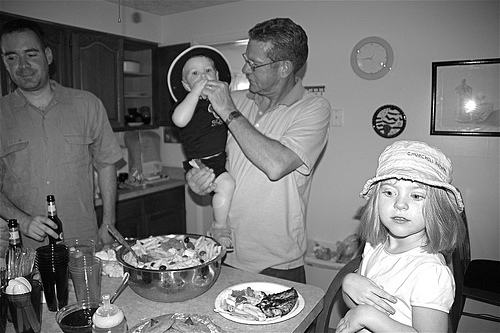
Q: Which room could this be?
A: It is a kitchen.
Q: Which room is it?
A: It is a kitchen.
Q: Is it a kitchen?
A: Yes, it is a kitchen.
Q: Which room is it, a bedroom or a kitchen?
A: It is a kitchen.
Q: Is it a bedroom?
A: No, it is a kitchen.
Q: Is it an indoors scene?
A: Yes, it is indoors.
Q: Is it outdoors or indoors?
A: It is indoors.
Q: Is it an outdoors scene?
A: No, it is indoors.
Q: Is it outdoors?
A: No, it is indoors.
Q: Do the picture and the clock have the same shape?
A: Yes, both the picture and the clock are round.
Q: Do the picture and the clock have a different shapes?
A: No, both the picture and the clock are round.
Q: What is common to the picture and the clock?
A: The shape, both the picture and the clock are round.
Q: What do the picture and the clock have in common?
A: The shape, both the picture and the clock are round.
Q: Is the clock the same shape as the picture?
A: Yes, both the clock and the picture are round.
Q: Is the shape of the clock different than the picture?
A: No, both the clock and the picture are round.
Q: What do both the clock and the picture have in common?
A: The shape, both the clock and the picture are round.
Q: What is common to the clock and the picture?
A: The shape, both the clock and the picture are round.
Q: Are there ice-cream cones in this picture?
A: No, there are no ice-cream cones.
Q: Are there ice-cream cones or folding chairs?
A: No, there are no ice-cream cones or folding chairs.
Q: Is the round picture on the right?
A: Yes, the picture is on the right of the image.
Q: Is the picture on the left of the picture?
A: No, the picture is on the right of the image.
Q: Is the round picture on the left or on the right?
A: The picture is on the right of the image.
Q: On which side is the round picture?
A: The picture is on the right of the image.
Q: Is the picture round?
A: Yes, the picture is round.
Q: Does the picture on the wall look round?
A: Yes, the picture is round.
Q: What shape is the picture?
A: The picture is round.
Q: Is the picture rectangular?
A: No, the picture is round.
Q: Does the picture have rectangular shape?
A: No, the picture is round.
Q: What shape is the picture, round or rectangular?
A: The picture is round.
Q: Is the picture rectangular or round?
A: The picture is round.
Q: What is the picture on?
A: The picture is on the wall.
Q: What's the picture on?
A: The picture is on the wall.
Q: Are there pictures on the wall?
A: Yes, there is a picture on the wall.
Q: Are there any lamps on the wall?
A: No, there is a picture on the wall.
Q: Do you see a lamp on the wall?
A: No, there is a picture on the wall.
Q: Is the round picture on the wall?
A: Yes, the picture is on the wall.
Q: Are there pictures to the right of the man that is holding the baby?
A: Yes, there is a picture to the right of the man.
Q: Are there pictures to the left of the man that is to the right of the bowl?
A: No, the picture is to the right of the man.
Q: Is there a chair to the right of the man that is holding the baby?
A: No, there is a picture to the right of the man.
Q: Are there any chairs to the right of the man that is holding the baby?
A: No, there is a picture to the right of the man.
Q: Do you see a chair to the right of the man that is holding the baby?
A: No, there is a picture to the right of the man.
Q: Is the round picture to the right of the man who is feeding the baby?
A: Yes, the picture is to the right of the man.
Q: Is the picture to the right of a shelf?
A: No, the picture is to the right of the man.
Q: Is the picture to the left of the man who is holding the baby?
A: No, the picture is to the right of the man.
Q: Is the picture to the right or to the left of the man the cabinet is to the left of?
A: The picture is to the right of the man.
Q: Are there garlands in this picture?
A: No, there are no garlands.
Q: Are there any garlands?
A: No, there are no garlands.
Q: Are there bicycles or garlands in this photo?
A: No, there are no garlands or bicycles.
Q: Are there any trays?
A: No, there are no trays.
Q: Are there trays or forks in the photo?
A: No, there are no trays or forks.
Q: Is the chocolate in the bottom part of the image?
A: Yes, the chocolate is in the bottom of the image.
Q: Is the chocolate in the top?
A: No, the chocolate is in the bottom of the image.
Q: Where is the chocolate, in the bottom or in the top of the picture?
A: The chocolate is in the bottom of the image.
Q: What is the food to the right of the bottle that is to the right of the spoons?
A: The food is chocolate.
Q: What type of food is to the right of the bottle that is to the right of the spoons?
A: The food is chocolate.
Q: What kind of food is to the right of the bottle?
A: The food is chocolate.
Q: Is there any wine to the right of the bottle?
A: No, there is chocolate to the right of the bottle.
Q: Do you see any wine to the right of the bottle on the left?
A: No, there is chocolate to the right of the bottle.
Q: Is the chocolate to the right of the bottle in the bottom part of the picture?
A: Yes, the chocolate is to the right of the bottle.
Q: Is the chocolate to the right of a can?
A: No, the chocolate is to the right of the bottle.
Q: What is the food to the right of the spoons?
A: The food is chocolate.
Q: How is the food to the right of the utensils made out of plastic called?
A: The food is chocolate.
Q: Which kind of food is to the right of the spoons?
A: The food is chocolate.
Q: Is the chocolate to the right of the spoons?
A: Yes, the chocolate is to the right of the spoons.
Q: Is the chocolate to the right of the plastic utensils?
A: Yes, the chocolate is to the right of the spoons.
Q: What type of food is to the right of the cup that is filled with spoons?
A: The food is chocolate.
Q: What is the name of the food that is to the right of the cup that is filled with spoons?
A: The food is chocolate.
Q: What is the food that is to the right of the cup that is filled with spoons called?
A: The food is chocolate.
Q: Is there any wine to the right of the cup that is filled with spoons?
A: No, there is chocolate to the right of the cup.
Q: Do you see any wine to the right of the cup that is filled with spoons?
A: No, there is chocolate to the right of the cup.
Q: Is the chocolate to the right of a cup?
A: Yes, the chocolate is to the right of a cup.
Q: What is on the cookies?
A: The chocolate is on the cookies.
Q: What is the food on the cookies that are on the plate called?
A: The food is chocolate.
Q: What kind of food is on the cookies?
A: The food is chocolate.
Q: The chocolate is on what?
A: The chocolate is on the cookies.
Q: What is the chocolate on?
A: The chocolate is on the cookies.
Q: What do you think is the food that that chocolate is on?
A: The food is cookies.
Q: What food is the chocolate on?
A: The chocolate is on the cookies.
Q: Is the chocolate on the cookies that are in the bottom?
A: Yes, the chocolate is on the cookies.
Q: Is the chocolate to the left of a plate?
A: Yes, the chocolate is to the left of a plate.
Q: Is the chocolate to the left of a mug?
A: No, the chocolate is to the left of a plate.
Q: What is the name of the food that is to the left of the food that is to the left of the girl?
A: The food is chocolate.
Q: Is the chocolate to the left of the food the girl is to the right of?
A: Yes, the chocolate is to the left of the food.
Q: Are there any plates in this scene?
A: Yes, there is a plate.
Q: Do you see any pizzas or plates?
A: Yes, there is a plate.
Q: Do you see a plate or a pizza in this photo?
A: Yes, there is a plate.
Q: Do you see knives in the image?
A: No, there are no knives.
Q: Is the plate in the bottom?
A: Yes, the plate is in the bottom of the image.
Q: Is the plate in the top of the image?
A: No, the plate is in the bottom of the image.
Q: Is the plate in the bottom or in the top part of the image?
A: The plate is in the bottom of the image.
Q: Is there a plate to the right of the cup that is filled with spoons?
A: Yes, there is a plate to the right of the cup.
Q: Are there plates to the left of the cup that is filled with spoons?
A: No, the plate is to the right of the cup.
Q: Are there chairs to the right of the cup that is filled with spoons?
A: No, there is a plate to the right of the cup.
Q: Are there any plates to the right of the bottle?
A: Yes, there is a plate to the right of the bottle.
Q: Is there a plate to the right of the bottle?
A: Yes, there is a plate to the right of the bottle.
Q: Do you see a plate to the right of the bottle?
A: Yes, there is a plate to the right of the bottle.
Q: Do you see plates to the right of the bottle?
A: Yes, there is a plate to the right of the bottle.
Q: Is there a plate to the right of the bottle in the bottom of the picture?
A: Yes, there is a plate to the right of the bottle.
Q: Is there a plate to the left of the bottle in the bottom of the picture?
A: No, the plate is to the right of the bottle.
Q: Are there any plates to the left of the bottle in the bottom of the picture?
A: No, the plate is to the right of the bottle.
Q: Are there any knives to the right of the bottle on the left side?
A: No, there is a plate to the right of the bottle.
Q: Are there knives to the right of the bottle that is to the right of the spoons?
A: No, there is a plate to the right of the bottle.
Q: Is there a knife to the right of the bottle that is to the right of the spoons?
A: No, there is a plate to the right of the bottle.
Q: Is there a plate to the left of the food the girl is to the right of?
A: Yes, there is a plate to the left of the food.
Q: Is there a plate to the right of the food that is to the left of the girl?
A: No, the plate is to the left of the food.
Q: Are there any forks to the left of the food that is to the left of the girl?
A: No, there is a plate to the left of the food.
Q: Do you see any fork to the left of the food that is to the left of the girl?
A: No, there is a plate to the left of the food.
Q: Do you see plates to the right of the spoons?
A: Yes, there is a plate to the right of the spoons.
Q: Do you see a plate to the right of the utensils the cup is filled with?
A: Yes, there is a plate to the right of the spoons.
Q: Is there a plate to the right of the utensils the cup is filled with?
A: Yes, there is a plate to the right of the spoons.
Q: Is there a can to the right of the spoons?
A: No, there is a plate to the right of the spoons.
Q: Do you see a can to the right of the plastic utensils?
A: No, there is a plate to the right of the spoons.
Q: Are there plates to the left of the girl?
A: Yes, there is a plate to the left of the girl.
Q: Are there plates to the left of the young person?
A: Yes, there is a plate to the left of the girl.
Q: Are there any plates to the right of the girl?
A: No, the plate is to the left of the girl.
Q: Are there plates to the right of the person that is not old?
A: No, the plate is to the left of the girl.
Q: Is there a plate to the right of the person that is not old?
A: No, the plate is to the left of the girl.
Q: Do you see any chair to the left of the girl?
A: No, there is a plate to the left of the girl.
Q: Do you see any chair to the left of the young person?
A: No, there is a plate to the left of the girl.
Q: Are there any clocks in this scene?
A: Yes, there is a clock.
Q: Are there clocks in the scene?
A: Yes, there is a clock.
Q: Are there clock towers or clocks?
A: Yes, there is a clock.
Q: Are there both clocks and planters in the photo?
A: No, there is a clock but no planters.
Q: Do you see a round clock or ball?
A: Yes, there is a round clock.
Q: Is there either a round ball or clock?
A: Yes, there is a round clock.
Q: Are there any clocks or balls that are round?
A: Yes, the clock is round.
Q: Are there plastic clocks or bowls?
A: Yes, there is a plastic clock.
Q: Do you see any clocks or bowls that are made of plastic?
A: Yes, the clock is made of plastic.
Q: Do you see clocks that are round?
A: Yes, there is a round clock.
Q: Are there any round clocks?
A: Yes, there is a round clock.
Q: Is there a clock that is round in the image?
A: Yes, there is a round clock.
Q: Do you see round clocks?
A: Yes, there is a round clock.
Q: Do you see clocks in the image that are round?
A: Yes, there is a clock that is round.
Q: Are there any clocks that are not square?
A: Yes, there is a round clock.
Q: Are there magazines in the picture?
A: No, there are no magazines.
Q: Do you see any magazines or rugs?
A: No, there are no magazines or rugs.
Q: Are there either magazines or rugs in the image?
A: No, there are no magazines or rugs.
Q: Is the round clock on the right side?
A: Yes, the clock is on the right of the image.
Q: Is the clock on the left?
A: No, the clock is on the right of the image.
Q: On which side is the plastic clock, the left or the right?
A: The clock is on the right of the image.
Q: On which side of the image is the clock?
A: The clock is on the right of the image.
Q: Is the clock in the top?
A: Yes, the clock is in the top of the image.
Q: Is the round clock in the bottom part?
A: No, the clock is in the top of the image.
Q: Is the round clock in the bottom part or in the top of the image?
A: The clock is in the top of the image.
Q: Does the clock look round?
A: Yes, the clock is round.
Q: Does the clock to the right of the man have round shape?
A: Yes, the clock is round.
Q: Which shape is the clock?
A: The clock is round.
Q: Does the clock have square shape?
A: No, the clock is round.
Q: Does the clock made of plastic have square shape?
A: No, the clock is round.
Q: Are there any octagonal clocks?
A: No, there is a clock but it is round.